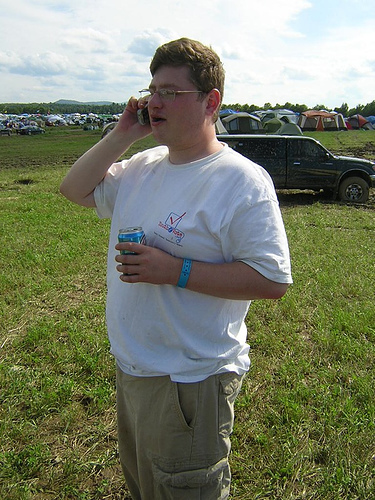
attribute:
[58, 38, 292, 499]
man — in white, talking, holding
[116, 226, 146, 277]
can — blue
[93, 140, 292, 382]
shirt — white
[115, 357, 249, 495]
pants — tan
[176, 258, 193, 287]
wrist band — BLUE 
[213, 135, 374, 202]
truck — black, parked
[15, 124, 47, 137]
car — parked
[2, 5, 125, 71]
cloud — white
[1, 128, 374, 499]
grass — green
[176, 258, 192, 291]
watch — blue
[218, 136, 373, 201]
car — green